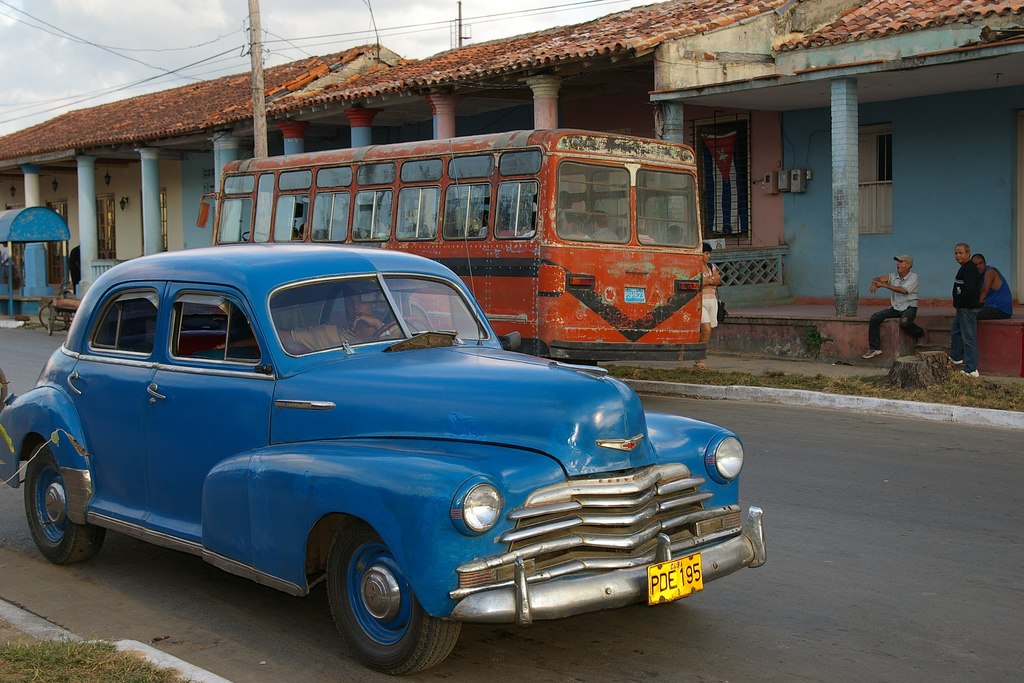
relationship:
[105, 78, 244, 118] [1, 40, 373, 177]
tiles on roof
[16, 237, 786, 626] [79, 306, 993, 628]
car on street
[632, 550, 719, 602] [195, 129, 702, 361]
plate on a bus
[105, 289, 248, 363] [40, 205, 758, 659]
windows on a vehicle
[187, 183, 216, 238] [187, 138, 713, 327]
mirror on a bus